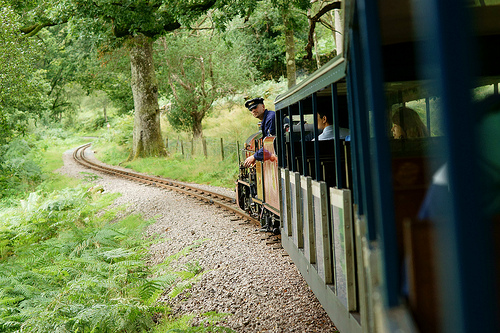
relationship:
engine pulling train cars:
[236, 132, 276, 233] [272, 1, 497, 331]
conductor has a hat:
[241, 97, 289, 170] [246, 97, 260, 108]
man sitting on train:
[311, 106, 344, 145] [239, 83, 436, 270]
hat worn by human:
[238, 91, 266, 104] [242, 94, 280, 170]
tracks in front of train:
[68, 141, 238, 220] [244, 0, 484, 326]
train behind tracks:
[244, 0, 484, 326] [68, 141, 238, 220]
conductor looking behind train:
[227, 96, 283, 148] [278, 83, 432, 279]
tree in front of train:
[149, 39, 232, 141] [226, 3, 480, 330]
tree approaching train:
[0, 0, 236, 167] [244, 0, 484, 326]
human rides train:
[304, 104, 351, 139] [244, 0, 484, 326]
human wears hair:
[389, 106, 429, 141] [394, 101, 431, 140]